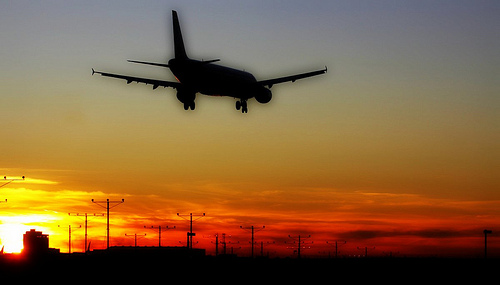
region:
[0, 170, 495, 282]
a picturesque sunset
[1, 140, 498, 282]
buildings and light poles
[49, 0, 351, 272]
a plane in final approach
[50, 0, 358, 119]
a plane about to land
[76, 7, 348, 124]
a plane with its landing gear down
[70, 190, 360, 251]
rows of lighting for an airport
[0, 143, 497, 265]
clouds in the distance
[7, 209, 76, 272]
a building against the sun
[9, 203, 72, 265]
a silhouette against a bright sky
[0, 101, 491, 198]
an eerie green shade in the sky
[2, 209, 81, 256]
Where the sun is setting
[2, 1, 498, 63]
Portion of blue sky in the photo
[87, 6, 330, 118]
Outline of the airplane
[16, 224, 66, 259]
Outline of the building in front of the sunset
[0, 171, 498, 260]
Outline of the poles shown near the runway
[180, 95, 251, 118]
Landing gear of the plane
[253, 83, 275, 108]
Engine under the right wing of the plane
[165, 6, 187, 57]
Tail fin of the airplane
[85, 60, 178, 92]
Left wing of the plane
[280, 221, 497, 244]
Darkest clouds shown in the photo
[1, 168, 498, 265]
Red and orange clouds in the sunset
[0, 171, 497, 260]
The outline of the poles near the runway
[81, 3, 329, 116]
The airplane shown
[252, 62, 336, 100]
The Right wing of the plane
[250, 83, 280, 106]
The engine under the right wing of the plane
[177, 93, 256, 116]
The landing gear of the plane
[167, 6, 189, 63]
The tail fin of the plane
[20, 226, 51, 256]
Building in front of the sunset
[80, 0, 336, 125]
A plane in the sky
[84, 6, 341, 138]
Plane is looking dark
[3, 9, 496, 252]
Sky is blue, yellow and red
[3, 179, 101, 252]
Sun in the horizon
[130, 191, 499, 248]
Sky is red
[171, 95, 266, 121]
Wheels of plane are visible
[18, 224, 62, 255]
A tall building in the background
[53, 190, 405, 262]
Poles are in line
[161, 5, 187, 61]
Vertical stabilizer of plane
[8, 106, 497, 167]
Yellow sky color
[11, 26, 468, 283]
a beautiful sunset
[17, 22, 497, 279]
evening sky over a flat land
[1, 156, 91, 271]
the setting sun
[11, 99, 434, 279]
whispy clouds low in the sky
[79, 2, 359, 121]
the outline of a plane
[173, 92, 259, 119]
the landing gear of a plane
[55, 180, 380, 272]
a bunch of telephone poles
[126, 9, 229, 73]
tail of a plane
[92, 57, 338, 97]
a set of wings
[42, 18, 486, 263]
an evening scene